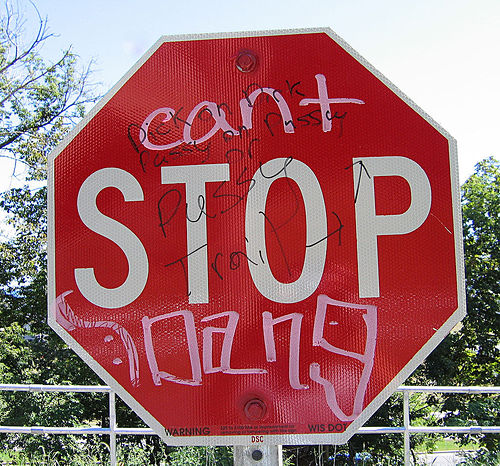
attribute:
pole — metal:
[232, 431, 264, 464]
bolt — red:
[231, 394, 278, 431]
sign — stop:
[21, 35, 483, 451]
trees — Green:
[470, 176, 498, 223]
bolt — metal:
[234, 47, 255, 72]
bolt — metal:
[242, 392, 269, 420]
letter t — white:
[146, 158, 236, 316]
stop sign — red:
[25, 30, 463, 447]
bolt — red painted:
[241, 397, 268, 422]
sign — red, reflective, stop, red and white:
[45, 24, 468, 450]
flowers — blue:
[330, 445, 374, 463]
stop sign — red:
[33, 43, 496, 408]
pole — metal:
[230, 445, 282, 465]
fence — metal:
[1, 380, 499, 462]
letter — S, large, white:
[53, 157, 203, 345]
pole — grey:
[230, 442, 285, 464]